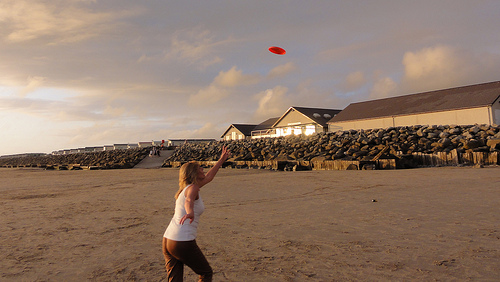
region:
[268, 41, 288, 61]
this is a kite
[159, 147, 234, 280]
this is a lady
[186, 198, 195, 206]
the lady is light skinned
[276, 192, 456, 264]
this is a ground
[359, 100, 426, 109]
this is a roof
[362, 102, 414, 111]
the roof is brown in color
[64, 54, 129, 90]
this is a sky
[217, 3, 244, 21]
the sky is blue in color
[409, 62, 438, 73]
this is a cloud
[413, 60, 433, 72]
the cloud is white in color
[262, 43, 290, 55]
The red Frisbee in the air.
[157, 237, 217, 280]
The brown pants worn by the girl.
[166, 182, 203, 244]
The white tank top worn by the girl.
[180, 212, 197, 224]
The girl's right hand.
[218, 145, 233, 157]
The girl's left hand in the air.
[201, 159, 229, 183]
The girl's left arm in the air.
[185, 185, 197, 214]
The girl's right arm extended outwards.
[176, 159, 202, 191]
The girl's blond hair.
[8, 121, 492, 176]
The pile of rocks running across the beach.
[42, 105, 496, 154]
The row of houses along the beach.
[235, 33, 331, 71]
large red Frisbee in the air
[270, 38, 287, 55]
black logo on frisbee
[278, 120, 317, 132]
white doors on brown house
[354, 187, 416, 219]
black rock in sand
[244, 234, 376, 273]
lines in brown sand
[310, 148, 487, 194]
brown barriers in the sand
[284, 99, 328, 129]
triangular roof on house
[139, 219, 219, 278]
woman wearing brown pants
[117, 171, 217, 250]
short sleeve white tee shirt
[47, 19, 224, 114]
gray clouds in the sky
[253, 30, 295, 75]
a red frisbee in the air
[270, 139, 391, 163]
a pile of large rocks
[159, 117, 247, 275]
a woman throwing a frisbee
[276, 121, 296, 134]
light reflecting off the windows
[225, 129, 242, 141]
windows on a house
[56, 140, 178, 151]
houses lining the beach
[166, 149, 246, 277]
a woman wearing a white shirt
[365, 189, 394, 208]
a ball lying on the beach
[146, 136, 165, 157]
people walking down the boardwalk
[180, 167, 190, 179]
blond hair on a head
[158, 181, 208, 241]
the woman is wearing a white top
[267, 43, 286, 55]
the Frisbee is up in the air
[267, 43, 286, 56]
the Frisbee is red in color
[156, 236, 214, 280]
the woman is wearing brown shorts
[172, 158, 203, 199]
the woman has brown hair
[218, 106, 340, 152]
two houses are in the background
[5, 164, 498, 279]
the sand is in the background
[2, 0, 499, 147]
many clouds are in the sky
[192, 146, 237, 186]
the woman has arm raised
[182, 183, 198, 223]
the woman has her arm extended